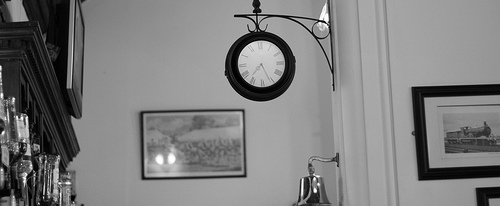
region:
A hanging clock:
[225, 27, 310, 104]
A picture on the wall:
[134, 99, 251, 183]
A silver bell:
[290, 153, 342, 204]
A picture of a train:
[402, 88, 498, 168]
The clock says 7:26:
[239, 57, 277, 88]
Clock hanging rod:
[243, 0, 351, 75]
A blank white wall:
[98, 18, 197, 88]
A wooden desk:
[8, 28, 83, 163]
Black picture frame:
[406, 80, 441, 178]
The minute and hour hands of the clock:
[250, 62, 269, 83]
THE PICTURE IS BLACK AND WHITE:
[126, 100, 256, 184]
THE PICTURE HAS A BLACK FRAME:
[403, 76, 499, 181]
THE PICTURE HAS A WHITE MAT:
[401, 77, 498, 180]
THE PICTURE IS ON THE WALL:
[409, 70, 498, 180]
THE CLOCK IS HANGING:
[221, 2, 339, 105]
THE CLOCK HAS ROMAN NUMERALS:
[232, 38, 285, 96]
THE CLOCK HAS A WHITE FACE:
[230, 33, 286, 96]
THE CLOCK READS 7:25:
[221, 0, 338, 106]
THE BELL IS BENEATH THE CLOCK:
[222, 2, 343, 104]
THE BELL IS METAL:
[289, 150, 344, 205]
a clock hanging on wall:
[201, 4, 476, 126]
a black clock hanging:
[211, 6, 399, 123]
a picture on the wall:
[107, 74, 310, 204]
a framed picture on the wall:
[119, 77, 304, 202]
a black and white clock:
[186, 12, 393, 117]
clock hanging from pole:
[225, 7, 443, 133]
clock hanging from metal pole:
[207, 0, 457, 135]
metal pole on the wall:
[229, 6, 464, 144]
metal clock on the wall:
[215, 3, 471, 153]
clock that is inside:
[208, 2, 410, 119]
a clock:
[226, 35, 293, 105]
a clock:
[256, 52, 308, 107]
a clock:
[198, 21, 381, 173]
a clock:
[206, 5, 299, 110]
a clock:
[228, 52, 308, 148]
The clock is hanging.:
[207, 21, 307, 108]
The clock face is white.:
[238, 40, 286, 84]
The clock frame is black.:
[206, 24, 299, 99]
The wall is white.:
[106, 16, 225, 83]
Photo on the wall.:
[121, 102, 283, 187]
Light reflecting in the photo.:
[146, 143, 203, 177]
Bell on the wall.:
[279, 153, 346, 204]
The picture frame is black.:
[393, 78, 496, 182]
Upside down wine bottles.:
[6, 85, 78, 203]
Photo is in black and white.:
[1, 0, 498, 202]